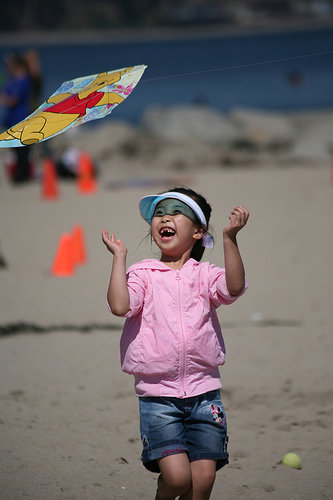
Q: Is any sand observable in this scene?
A: Yes, there is sand.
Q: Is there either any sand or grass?
A: Yes, there is sand.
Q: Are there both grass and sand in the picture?
A: No, there is sand but no grass.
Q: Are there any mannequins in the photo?
A: No, there are no mannequins.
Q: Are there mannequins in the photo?
A: No, there are no mannequins.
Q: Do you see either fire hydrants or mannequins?
A: No, there are no mannequins or fire hydrants.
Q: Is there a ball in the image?
A: Yes, there is a ball.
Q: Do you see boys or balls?
A: Yes, there is a ball.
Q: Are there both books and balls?
A: No, there is a ball but no books.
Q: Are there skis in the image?
A: No, there are no skis.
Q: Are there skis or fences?
A: No, there are no skis or fences.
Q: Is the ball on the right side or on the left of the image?
A: The ball is on the right of the image.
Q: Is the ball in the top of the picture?
A: No, the ball is in the bottom of the image.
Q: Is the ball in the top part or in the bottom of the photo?
A: The ball is in the bottom of the image.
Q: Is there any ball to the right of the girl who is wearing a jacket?
A: Yes, there is a ball to the right of the girl.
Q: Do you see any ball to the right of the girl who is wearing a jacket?
A: Yes, there is a ball to the right of the girl.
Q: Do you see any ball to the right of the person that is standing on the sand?
A: Yes, there is a ball to the right of the girl.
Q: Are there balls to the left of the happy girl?
A: No, the ball is to the right of the girl.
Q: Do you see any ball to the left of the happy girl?
A: No, the ball is to the right of the girl.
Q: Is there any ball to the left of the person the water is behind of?
A: No, the ball is to the right of the girl.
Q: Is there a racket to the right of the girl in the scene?
A: No, there is a ball to the right of the girl.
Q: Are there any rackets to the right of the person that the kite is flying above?
A: No, there is a ball to the right of the girl.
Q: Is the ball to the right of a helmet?
A: No, the ball is to the right of the girl.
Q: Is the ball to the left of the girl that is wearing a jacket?
A: No, the ball is to the right of the girl.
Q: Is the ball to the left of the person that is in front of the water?
A: No, the ball is to the right of the girl.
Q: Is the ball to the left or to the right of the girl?
A: The ball is to the right of the girl.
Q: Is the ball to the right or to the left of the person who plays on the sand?
A: The ball is to the right of the girl.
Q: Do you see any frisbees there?
A: No, there are no frisbees.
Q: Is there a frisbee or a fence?
A: No, there are no frisbees or fences.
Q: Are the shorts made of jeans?
A: Yes, the shorts are made of jeans.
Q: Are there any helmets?
A: No, there are no helmets.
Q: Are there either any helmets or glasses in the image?
A: No, there are no helmets or glasses.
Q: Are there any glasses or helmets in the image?
A: No, there are no helmets or glasses.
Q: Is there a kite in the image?
A: Yes, there is a kite.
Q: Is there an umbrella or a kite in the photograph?
A: Yes, there is a kite.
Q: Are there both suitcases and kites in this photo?
A: No, there is a kite but no suitcases.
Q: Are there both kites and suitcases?
A: No, there is a kite but no suitcases.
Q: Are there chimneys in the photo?
A: No, there are no chimneys.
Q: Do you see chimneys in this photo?
A: No, there are no chimneys.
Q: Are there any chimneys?
A: No, there are no chimneys.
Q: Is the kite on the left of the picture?
A: Yes, the kite is on the left of the image.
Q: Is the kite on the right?
A: No, the kite is on the left of the image.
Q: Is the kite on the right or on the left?
A: The kite is on the left of the image.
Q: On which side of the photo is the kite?
A: The kite is on the left of the image.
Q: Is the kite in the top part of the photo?
A: Yes, the kite is in the top of the image.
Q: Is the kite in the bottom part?
A: No, the kite is in the top of the image.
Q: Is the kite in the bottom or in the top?
A: The kite is in the top of the image.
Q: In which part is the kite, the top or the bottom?
A: The kite is in the top of the image.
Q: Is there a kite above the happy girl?
A: Yes, there is a kite above the girl.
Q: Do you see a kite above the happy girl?
A: Yes, there is a kite above the girl.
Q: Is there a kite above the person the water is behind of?
A: Yes, there is a kite above the girl.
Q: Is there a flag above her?
A: No, there is a kite above the girl.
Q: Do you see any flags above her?
A: No, there is a kite above the girl.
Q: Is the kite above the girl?
A: Yes, the kite is above the girl.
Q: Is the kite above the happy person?
A: Yes, the kite is above the girl.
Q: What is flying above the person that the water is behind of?
A: The kite is flying above the girl.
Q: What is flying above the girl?
A: The kite is flying above the girl.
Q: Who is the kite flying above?
A: The kite is flying above the girl.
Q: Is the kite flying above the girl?
A: Yes, the kite is flying above the girl.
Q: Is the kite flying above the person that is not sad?
A: Yes, the kite is flying above the girl.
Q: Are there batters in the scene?
A: No, there are no batters.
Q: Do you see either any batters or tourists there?
A: No, there are no batters or tourists.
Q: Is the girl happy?
A: Yes, the girl is happy.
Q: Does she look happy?
A: Yes, the girl is happy.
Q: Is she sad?
A: No, the girl is happy.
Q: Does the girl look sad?
A: No, the girl is happy.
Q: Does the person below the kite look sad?
A: No, the girl is happy.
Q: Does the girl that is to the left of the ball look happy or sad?
A: The girl is happy.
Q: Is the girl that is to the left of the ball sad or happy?
A: The girl is happy.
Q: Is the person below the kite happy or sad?
A: The girl is happy.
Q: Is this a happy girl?
A: Yes, this is a happy girl.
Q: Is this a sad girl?
A: No, this is a happy girl.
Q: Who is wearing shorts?
A: The girl is wearing shorts.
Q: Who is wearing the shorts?
A: The girl is wearing shorts.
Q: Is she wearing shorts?
A: Yes, the girl is wearing shorts.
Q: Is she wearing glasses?
A: No, the girl is wearing shorts.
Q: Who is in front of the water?
A: The girl is in front of the water.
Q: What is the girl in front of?
A: The girl is in front of the water.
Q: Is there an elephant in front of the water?
A: No, there is a girl in front of the water.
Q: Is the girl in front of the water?
A: Yes, the girl is in front of the water.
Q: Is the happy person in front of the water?
A: Yes, the girl is in front of the water.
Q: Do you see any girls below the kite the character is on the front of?
A: Yes, there is a girl below the kite.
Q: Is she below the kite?
A: Yes, the girl is below the kite.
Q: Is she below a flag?
A: No, the girl is below the kite.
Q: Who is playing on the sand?
A: The girl is playing on the sand.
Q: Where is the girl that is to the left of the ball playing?
A: The girl is playing on the sand.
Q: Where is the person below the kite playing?
A: The girl is playing on the sand.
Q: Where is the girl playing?
A: The girl is playing on the sand.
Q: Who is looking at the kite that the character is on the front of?
A: The girl is looking at the kite.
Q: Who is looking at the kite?
A: The girl is looking at the kite.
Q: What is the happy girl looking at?
A: The girl is looking at the kite.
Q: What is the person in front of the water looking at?
A: The girl is looking at the kite.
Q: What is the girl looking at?
A: The girl is looking at the kite.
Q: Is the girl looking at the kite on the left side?
A: Yes, the girl is looking at the kite.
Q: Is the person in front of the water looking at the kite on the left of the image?
A: Yes, the girl is looking at the kite.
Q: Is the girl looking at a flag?
A: No, the girl is looking at the kite.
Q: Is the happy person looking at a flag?
A: No, the girl is looking at the kite.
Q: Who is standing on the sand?
A: The girl is standing on the sand.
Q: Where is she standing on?
A: The girl is standing on the sand.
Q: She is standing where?
A: The girl is standing on the sand.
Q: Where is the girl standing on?
A: The girl is standing on the sand.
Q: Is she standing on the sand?
A: Yes, the girl is standing on the sand.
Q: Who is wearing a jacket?
A: The girl is wearing a jacket.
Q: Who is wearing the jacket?
A: The girl is wearing a jacket.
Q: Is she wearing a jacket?
A: Yes, the girl is wearing a jacket.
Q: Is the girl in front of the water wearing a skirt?
A: No, the girl is wearing a jacket.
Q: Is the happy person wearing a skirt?
A: No, the girl is wearing a jacket.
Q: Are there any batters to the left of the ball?
A: No, there is a girl to the left of the ball.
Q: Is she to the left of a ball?
A: Yes, the girl is to the left of a ball.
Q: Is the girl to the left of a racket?
A: No, the girl is to the left of a ball.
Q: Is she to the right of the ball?
A: No, the girl is to the left of the ball.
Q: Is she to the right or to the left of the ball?
A: The girl is to the left of the ball.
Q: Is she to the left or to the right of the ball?
A: The girl is to the left of the ball.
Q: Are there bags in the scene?
A: No, there are no bags.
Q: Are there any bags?
A: No, there are no bags.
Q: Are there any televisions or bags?
A: No, there are no bags or televisions.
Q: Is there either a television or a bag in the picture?
A: No, there are no bags or televisions.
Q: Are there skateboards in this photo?
A: No, there are no skateboards.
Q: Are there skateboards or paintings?
A: No, there are no skateboards or paintings.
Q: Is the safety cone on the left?
A: Yes, the safety cone is on the left of the image.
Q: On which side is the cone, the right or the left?
A: The cone is on the left of the image.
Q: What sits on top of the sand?
A: The traffic cone sits on top of the sand.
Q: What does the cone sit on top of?
A: The safety cone sits on top of the sand.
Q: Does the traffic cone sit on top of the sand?
A: Yes, the traffic cone sits on top of the sand.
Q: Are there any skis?
A: No, there are no skis.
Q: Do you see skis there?
A: No, there are no skis.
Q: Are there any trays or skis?
A: No, there are no skis or trays.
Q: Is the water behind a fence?
A: No, the water is behind the girl.